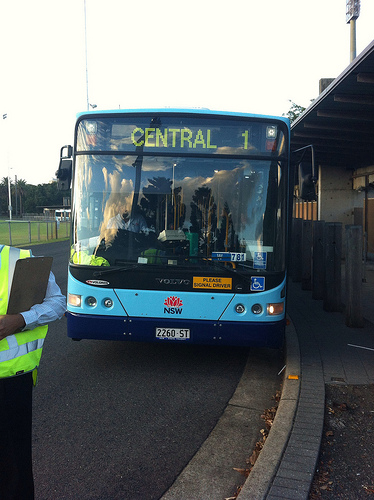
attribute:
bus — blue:
[53, 110, 317, 347]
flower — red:
[160, 293, 187, 310]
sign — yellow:
[127, 125, 267, 157]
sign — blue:
[249, 271, 268, 294]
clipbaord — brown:
[2, 256, 55, 317]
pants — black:
[0, 372, 38, 499]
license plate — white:
[157, 328, 192, 342]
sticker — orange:
[189, 274, 233, 295]